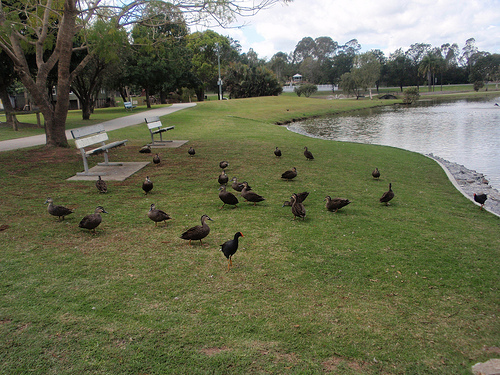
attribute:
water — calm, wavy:
[293, 87, 493, 218]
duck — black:
[218, 226, 243, 265]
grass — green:
[6, 90, 499, 374]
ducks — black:
[41, 136, 400, 269]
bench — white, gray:
[144, 116, 176, 148]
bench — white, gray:
[74, 123, 129, 174]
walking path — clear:
[3, 88, 195, 153]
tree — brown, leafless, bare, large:
[1, 2, 264, 147]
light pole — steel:
[214, 52, 230, 99]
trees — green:
[1, 2, 500, 111]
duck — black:
[283, 163, 297, 180]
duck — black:
[187, 146, 199, 154]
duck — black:
[140, 175, 159, 195]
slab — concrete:
[152, 134, 191, 150]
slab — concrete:
[75, 160, 147, 185]